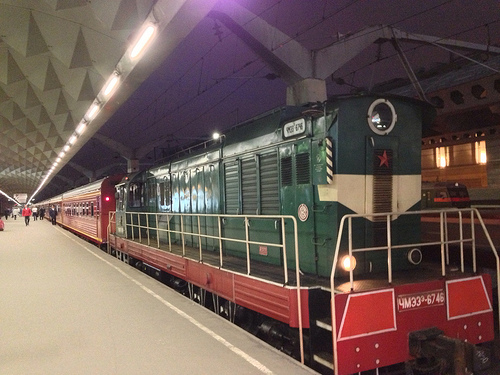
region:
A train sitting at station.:
[22, 38, 492, 373]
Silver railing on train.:
[107, 203, 498, 288]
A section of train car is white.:
[311, 162, 426, 217]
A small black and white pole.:
[321, 135, 339, 189]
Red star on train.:
[374, 143, 395, 170]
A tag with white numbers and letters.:
[384, 280, 451, 314]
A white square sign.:
[277, 118, 311, 140]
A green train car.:
[118, 114, 421, 268]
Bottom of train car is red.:
[108, 226, 499, 363]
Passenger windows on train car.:
[58, 193, 104, 223]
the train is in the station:
[1, 162, 139, 254]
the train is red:
[0, 171, 120, 243]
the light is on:
[95, 188, 116, 212]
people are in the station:
[5, 183, 70, 230]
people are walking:
[2, 191, 72, 235]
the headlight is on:
[301, 232, 397, 287]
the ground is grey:
[2, 227, 186, 359]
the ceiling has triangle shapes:
[0, 26, 101, 182]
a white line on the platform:
[19, 215, 204, 335]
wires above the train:
[80, 48, 293, 169]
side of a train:
[299, 242, 314, 256]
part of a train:
[222, 240, 233, 285]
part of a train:
[375, 161, 387, 172]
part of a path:
[196, 337, 212, 352]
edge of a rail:
[140, 272, 170, 327]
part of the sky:
[177, 95, 184, 110]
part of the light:
[62, 107, 68, 123]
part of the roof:
[90, 95, 95, 110]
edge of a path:
[142, 265, 165, 298]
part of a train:
[347, 145, 371, 190]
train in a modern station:
[18, 13, 483, 363]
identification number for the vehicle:
[395, 290, 445, 306]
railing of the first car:
[330, 210, 490, 275]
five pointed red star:
[370, 141, 396, 171]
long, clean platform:
[25, 270, 155, 370]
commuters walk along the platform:
[5, 195, 55, 225]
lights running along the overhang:
[80, 50, 145, 115]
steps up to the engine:
[300, 280, 340, 370]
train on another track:
[420, 170, 475, 215]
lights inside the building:
[421, 125, 496, 175]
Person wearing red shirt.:
[16, 205, 61, 217]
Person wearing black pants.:
[17, 212, 41, 232]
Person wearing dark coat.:
[42, 205, 59, 220]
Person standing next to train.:
[40, 200, 80, 228]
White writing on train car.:
[391, 278, 465, 305]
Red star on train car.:
[371, 148, 401, 173]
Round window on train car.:
[367, 100, 409, 133]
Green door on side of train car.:
[150, 183, 172, 232]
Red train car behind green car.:
[58, 178, 114, 248]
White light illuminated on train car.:
[328, 250, 377, 284]